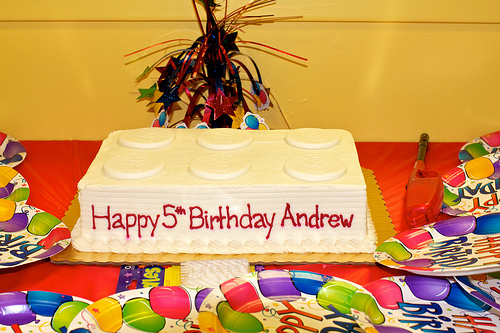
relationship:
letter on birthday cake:
[90, 203, 354, 240] [69, 127, 378, 256]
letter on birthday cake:
[246, 203, 266, 232] [69, 127, 378, 256]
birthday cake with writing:
[69, 127, 378, 256] [86, 203, 357, 232]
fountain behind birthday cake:
[121, 0, 309, 129] [69, 127, 378, 256]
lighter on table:
[403, 132, 443, 224] [0, 137, 460, 329]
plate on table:
[0, 131, 499, 332] [4, 139, 484, 315]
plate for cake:
[0, 131, 499, 332] [78, 130, 372, 250]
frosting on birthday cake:
[72, 127, 373, 251] [69, 127, 378, 256]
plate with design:
[67, 287, 218, 330] [68, 288, 221, 328]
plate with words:
[0, 131, 499, 332] [425, 235, 499, 265]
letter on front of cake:
[90, 203, 354, 240] [47, 92, 429, 269]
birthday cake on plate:
[69, 127, 378, 256] [0, 131, 499, 332]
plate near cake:
[0, 131, 499, 332] [44, 88, 418, 294]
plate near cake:
[0, 131, 499, 332] [30, 70, 373, 254]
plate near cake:
[0, 131, 499, 332] [85, 124, 397, 257]